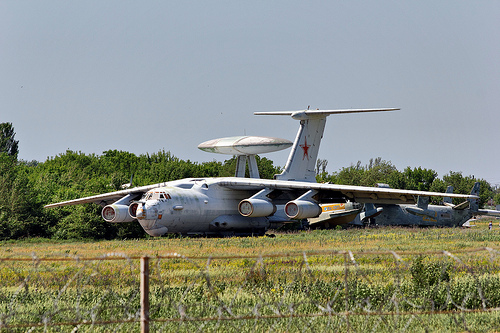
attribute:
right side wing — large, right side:
[42, 176, 164, 213]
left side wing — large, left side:
[219, 173, 480, 200]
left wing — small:
[329, 106, 404, 116]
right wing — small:
[252, 107, 295, 120]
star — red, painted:
[300, 137, 313, 163]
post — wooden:
[139, 253, 152, 332]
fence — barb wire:
[1, 247, 498, 332]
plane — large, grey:
[41, 108, 481, 239]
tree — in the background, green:
[11, 166, 49, 235]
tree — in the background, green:
[0, 120, 20, 194]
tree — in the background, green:
[403, 163, 440, 191]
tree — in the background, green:
[443, 169, 466, 193]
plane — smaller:
[322, 180, 484, 228]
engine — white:
[236, 188, 279, 219]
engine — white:
[284, 190, 323, 220]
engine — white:
[101, 197, 128, 225]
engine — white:
[127, 200, 139, 218]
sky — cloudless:
[2, 0, 499, 106]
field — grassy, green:
[1, 227, 498, 332]